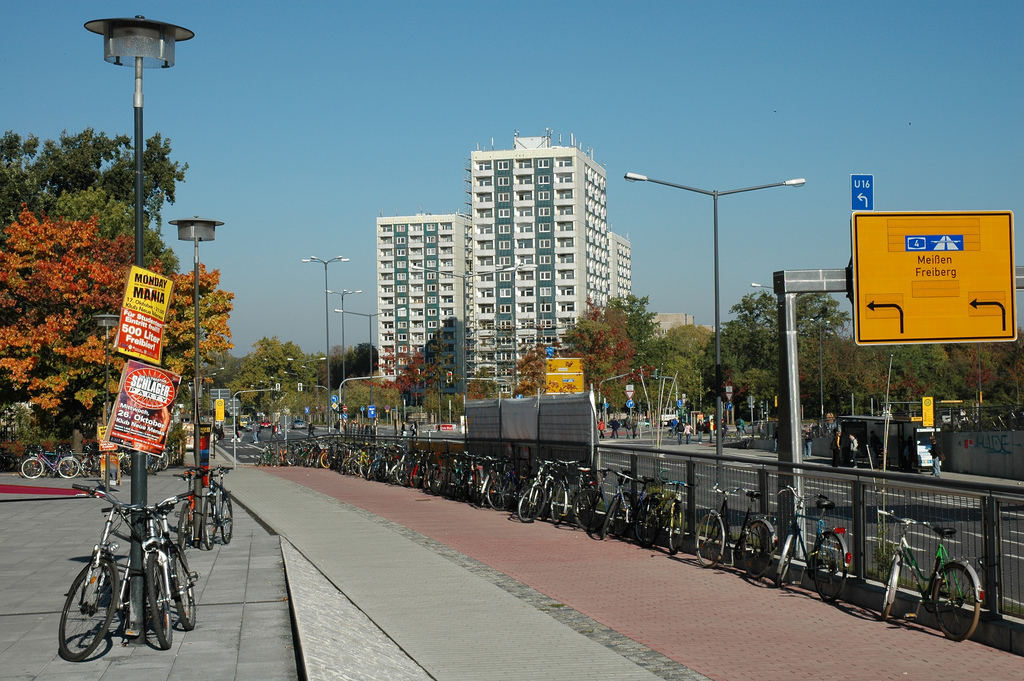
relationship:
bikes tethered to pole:
[54, 487, 201, 656] [93, 67, 163, 634]